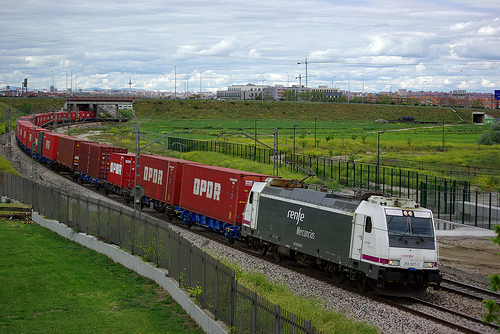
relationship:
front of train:
[374, 203, 444, 286] [8, 109, 446, 304]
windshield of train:
[384, 213, 438, 253] [8, 109, 446, 304]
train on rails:
[8, 109, 446, 304] [167, 223, 500, 333]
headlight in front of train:
[385, 259, 396, 266] [8, 109, 446, 304]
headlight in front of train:
[425, 262, 434, 269] [8, 109, 446, 304]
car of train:
[35, 130, 46, 156] [8, 109, 446, 304]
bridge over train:
[61, 94, 137, 109] [8, 109, 446, 304]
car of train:
[177, 158, 285, 230] [8, 109, 446, 304]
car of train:
[103, 148, 143, 193] [8, 109, 446, 304]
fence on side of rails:
[1, 163, 323, 334] [167, 223, 500, 333]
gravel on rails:
[366, 305, 394, 322] [167, 223, 500, 333]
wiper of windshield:
[396, 226, 411, 241] [384, 213, 438, 253]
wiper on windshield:
[409, 225, 430, 244] [384, 213, 438, 253]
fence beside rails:
[163, 133, 500, 237] [167, 223, 500, 333]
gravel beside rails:
[366, 305, 394, 322] [167, 223, 500, 333]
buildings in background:
[6, 77, 499, 99] [0, 68, 499, 111]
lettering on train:
[281, 205, 308, 229] [8, 109, 446, 304]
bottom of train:
[175, 207, 237, 236] [8, 109, 446, 304]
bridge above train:
[61, 94, 137, 109] [8, 109, 446, 304]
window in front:
[362, 213, 375, 235] [374, 203, 444, 286]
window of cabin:
[362, 213, 375, 235] [348, 191, 447, 289]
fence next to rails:
[163, 133, 500, 237] [167, 223, 500, 333]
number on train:
[402, 261, 423, 268] [8, 109, 446, 304]